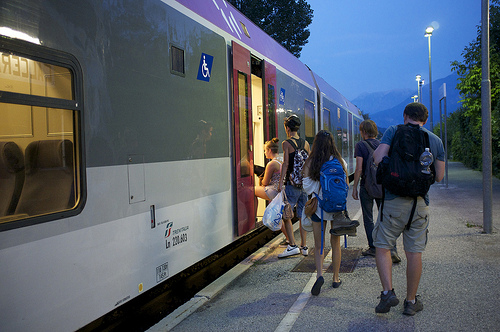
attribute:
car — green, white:
[0, 0, 318, 331]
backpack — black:
[375, 124, 436, 198]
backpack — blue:
[318, 157, 349, 214]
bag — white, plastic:
[261, 191, 285, 234]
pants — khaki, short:
[372, 197, 429, 253]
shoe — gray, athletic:
[373, 288, 400, 313]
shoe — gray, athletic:
[403, 298, 424, 316]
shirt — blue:
[379, 122, 445, 205]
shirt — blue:
[353, 138, 381, 188]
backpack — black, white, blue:
[289, 139, 309, 189]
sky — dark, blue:
[230, 2, 500, 102]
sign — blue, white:
[197, 52, 214, 82]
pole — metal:
[481, 2, 493, 233]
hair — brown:
[402, 101, 428, 123]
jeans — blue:
[360, 185, 398, 254]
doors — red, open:
[232, 38, 280, 237]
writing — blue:
[271, 203, 285, 230]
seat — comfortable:
[13, 140, 74, 215]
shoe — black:
[310, 276, 324, 296]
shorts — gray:
[265, 185, 281, 199]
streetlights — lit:
[411, 0, 493, 236]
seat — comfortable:
[1, 142, 23, 216]